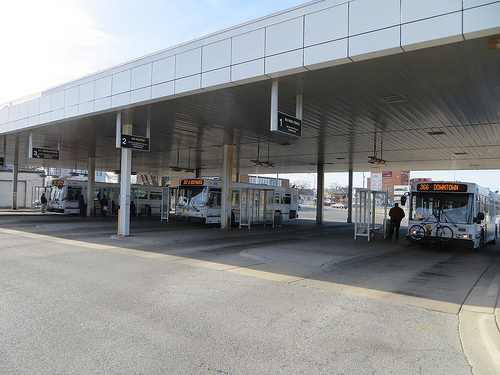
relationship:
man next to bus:
[385, 196, 405, 245] [400, 173, 497, 265]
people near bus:
[82, 196, 148, 227] [54, 161, 168, 219]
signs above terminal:
[34, 102, 302, 162] [7, 5, 498, 294]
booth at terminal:
[359, 189, 383, 238] [7, 5, 498, 294]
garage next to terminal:
[1, 168, 53, 201] [7, 5, 498, 294]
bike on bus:
[404, 214, 467, 245] [400, 173, 497, 265]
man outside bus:
[385, 196, 405, 245] [400, 173, 497, 265]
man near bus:
[385, 196, 405, 245] [400, 173, 497, 265]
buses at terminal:
[62, 178, 498, 277] [7, 5, 498, 294]